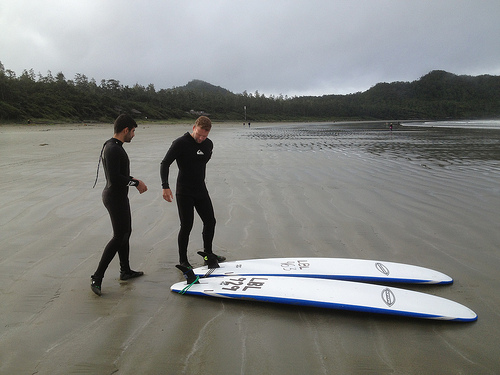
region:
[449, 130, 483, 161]
Ripples on the sand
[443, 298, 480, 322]
The tip of a surboard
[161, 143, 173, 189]
A man's arm in a wetsuit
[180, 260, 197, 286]
The fin on a surfboard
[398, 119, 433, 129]
A wave washing up on the shore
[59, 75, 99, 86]
Tips of pine trees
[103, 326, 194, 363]
Wet sand on a beach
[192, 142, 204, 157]
A white logo on a black wetsuit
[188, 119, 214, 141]
A man's face looking at a surfboard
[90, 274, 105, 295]
A man's foot on the sand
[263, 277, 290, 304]
edge of a board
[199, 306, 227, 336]
part of a beach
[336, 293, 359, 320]
part of a board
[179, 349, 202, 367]
part of a ground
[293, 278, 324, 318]
part of a board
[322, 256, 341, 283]
part of a board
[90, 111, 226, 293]
the men on the wet sand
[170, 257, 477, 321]
the surfboards on the wet sand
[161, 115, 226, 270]
the man standing on the wet sand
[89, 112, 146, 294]
the man standing on the wet sand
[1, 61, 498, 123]
the greenery in the distance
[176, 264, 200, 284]
the fin on the back of the surfboard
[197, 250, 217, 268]
the fin on the back of the surfboard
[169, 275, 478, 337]
the surfboard on the wet sand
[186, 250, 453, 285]
the surfboard on the wet sand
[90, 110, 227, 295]
the two men wearing wet suits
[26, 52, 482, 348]
Two men are at the beach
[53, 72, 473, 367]
Two men are checking their surfboards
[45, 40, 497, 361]
Two men are planning to surf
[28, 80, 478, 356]
Two men are wearing wetsuits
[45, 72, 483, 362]
Two men are standing in the sand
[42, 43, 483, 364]
Two men are close to the ocean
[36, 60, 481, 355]
Two men are enjoying their day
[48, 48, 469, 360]
The men are on vacation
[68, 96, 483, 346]
The men are experienced surfers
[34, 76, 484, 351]
The men enjoy water sports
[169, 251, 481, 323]
a couple of surf boards on a beach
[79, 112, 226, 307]
a couple of sufers on the beach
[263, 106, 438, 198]
the shore line of the beach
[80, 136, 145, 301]
a man in a black wet suit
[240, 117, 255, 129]
people walking on the beack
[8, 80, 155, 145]
a grassy bank on the beach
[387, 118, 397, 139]
a person on the water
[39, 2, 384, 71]
a gray cloudy sky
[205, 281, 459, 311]
a blue and white surf board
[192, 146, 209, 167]
writing on a wet suit